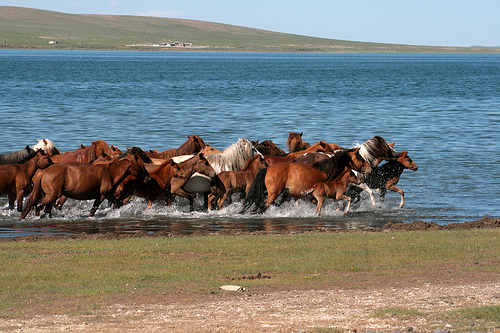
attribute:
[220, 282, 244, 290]
flat rock — bleached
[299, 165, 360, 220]
foal — brown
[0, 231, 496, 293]
grass — small patch, green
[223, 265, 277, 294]
brown dirt — dug up 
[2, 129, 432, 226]
horses — wild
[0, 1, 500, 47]
sky — clear, blue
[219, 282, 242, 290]
rock — White 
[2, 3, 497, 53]
hill — treeless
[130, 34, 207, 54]
buildings — white, brown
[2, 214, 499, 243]
mud — small heap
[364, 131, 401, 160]
head — brown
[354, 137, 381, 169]
mane — white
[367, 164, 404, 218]
horse leg — white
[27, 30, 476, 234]
water — blue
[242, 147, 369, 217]
horse — fully grown, adult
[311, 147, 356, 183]
mane — black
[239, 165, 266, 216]
tail — black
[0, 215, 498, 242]
dirt — dark brown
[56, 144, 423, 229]
horses — runing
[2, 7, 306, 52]
hill — green,  brown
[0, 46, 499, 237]
water — blue, rippled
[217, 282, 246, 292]
stone — small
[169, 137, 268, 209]
horse — full grown, adult, white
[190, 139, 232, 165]
head — tan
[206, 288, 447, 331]
patch dirt — small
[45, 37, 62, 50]
building — alone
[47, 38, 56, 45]
building — White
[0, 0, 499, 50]
hillside — green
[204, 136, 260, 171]
horse — white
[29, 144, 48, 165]
head — dark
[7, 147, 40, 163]
mane — dark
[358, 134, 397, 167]
mane — black, white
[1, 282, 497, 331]
patch — white